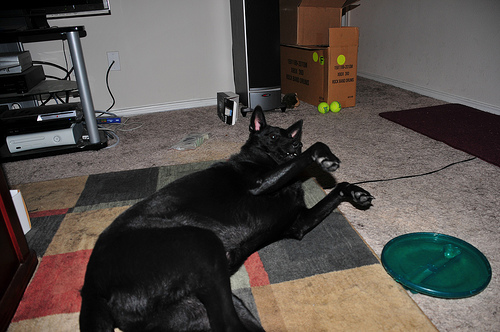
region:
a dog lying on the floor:
[76, 105, 374, 330]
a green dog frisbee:
[381, 222, 496, 302]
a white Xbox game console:
[0, 126, 87, 153]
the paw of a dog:
[349, 181, 376, 213]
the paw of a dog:
[313, 148, 341, 173]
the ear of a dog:
[243, 103, 266, 135]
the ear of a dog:
[285, 114, 305, 136]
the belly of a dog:
[176, 198, 287, 276]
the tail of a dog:
[65, 308, 112, 330]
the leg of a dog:
[289, 180, 376, 240]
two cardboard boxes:
[264, 5, 365, 112]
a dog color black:
[68, 96, 384, 328]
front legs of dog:
[253, 140, 374, 238]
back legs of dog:
[175, 260, 265, 330]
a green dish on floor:
[373, 220, 488, 300]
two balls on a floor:
[310, 95, 342, 118]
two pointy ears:
[245, 96, 307, 136]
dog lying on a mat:
[41, 97, 386, 328]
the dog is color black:
[60, 95, 376, 328]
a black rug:
[366, 83, 498, 188]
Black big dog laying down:
[75, 102, 375, 330]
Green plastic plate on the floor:
[378, 227, 494, 299]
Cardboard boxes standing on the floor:
[273, 2, 361, 107]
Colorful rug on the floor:
[33, 172, 88, 262]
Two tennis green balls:
[315, 97, 343, 115]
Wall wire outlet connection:
[105, 45, 122, 74]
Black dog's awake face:
[243, 102, 305, 169]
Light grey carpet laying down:
[342, 121, 392, 168]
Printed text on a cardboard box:
[326, 50, 355, 86]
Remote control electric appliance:
[2, 119, 84, 156]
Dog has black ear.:
[242, 110, 272, 132]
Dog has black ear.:
[288, 118, 310, 135]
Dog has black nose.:
[286, 135, 316, 166]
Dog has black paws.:
[301, 134, 384, 224]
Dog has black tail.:
[65, 285, 100, 322]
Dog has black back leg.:
[129, 224, 245, 316]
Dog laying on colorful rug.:
[85, 165, 336, 300]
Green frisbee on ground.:
[378, 215, 494, 315]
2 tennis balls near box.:
[311, 96, 370, 124]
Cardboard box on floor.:
[285, 64, 366, 111]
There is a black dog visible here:
[203, 141, 226, 216]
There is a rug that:
[297, 282, 329, 327]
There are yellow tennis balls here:
[320, 101, 333, 113]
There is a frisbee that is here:
[408, 225, 435, 292]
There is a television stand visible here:
[56, 73, 96, 138]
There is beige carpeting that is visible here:
[424, 182, 429, 194]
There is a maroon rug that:
[436, 113, 443, 133]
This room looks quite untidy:
[95, 47, 379, 302]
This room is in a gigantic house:
[93, 52, 340, 299]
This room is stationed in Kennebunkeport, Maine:
[98, 7, 313, 262]